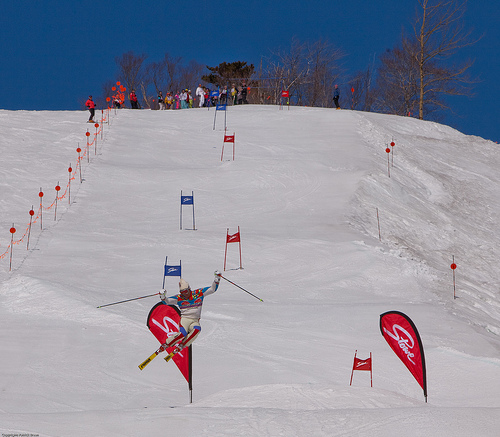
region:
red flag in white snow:
[132, 292, 214, 401]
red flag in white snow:
[345, 342, 398, 389]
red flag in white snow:
[371, 303, 450, 387]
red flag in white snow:
[415, 238, 459, 290]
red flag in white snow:
[221, 223, 270, 276]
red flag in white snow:
[207, 119, 254, 169]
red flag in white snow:
[375, 101, 416, 181]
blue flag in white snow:
[158, 254, 189, 282]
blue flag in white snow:
[175, 193, 201, 234]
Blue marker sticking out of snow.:
[212, 95, 239, 122]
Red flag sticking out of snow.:
[217, 123, 260, 175]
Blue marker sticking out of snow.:
[167, 190, 216, 243]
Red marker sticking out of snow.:
[211, 215, 260, 283]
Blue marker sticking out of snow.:
[151, 258, 212, 300]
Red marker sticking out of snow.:
[346, 333, 388, 421]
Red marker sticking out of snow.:
[438, 242, 477, 308]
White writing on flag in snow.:
[378, 316, 440, 396]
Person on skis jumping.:
[99, 252, 248, 406]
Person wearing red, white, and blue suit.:
[168, 273, 208, 378]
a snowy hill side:
[5, 105, 497, 435]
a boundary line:
[0, 94, 120, 279]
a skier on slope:
[81, 91, 98, 121]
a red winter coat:
[84, 99, 94, 109]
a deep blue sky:
[0, 0, 499, 137]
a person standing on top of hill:
[328, 82, 344, 108]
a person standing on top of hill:
[238, 82, 249, 102]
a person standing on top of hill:
[194, 82, 207, 105]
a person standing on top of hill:
[177, 90, 188, 106]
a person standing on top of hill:
[164, 88, 171, 107]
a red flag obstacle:
[348, 347, 375, 387]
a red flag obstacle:
[220, 224, 242, 271]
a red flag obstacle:
[217, 130, 240, 163]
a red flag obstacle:
[276, 85, 293, 107]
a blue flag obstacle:
[210, 95, 232, 130]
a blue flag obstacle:
[177, 186, 198, 231]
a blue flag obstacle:
[159, 255, 181, 288]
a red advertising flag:
[146, 296, 197, 402]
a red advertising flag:
[376, 306, 430, 401]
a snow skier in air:
[94, 266, 266, 373]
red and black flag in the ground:
[375, 312, 435, 402]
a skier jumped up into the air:
[100, 265, 242, 373]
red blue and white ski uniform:
[150, 277, 222, 356]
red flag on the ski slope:
[340, 349, 380, 389]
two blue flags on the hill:
[152, 189, 194, 297]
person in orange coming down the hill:
[82, 93, 102, 130]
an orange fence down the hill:
[2, 77, 141, 277]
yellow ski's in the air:
[135, 330, 199, 372]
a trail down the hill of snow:
[13, 104, 332, 424]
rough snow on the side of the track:
[381, 103, 497, 333]